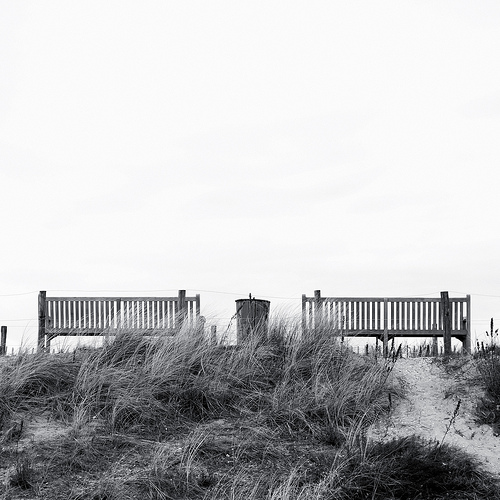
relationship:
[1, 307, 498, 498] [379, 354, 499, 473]
grass in sand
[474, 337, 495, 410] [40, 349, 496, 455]
bush on beach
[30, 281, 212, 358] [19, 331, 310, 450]
bench facing weeds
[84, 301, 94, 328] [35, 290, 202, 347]
vertical line on bench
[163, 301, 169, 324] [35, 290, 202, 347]
vertical line on bench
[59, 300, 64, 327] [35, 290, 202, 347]
vertical line on bench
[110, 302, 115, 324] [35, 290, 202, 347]
vertical line on bench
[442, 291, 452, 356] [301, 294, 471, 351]
post in front of bench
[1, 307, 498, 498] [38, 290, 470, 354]
grass growing high behind bench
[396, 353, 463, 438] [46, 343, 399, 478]
patch area near grass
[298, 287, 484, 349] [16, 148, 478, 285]
bench facing sky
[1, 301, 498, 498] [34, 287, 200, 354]
weeds growing in front of bench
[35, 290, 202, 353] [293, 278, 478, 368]
bench next to bench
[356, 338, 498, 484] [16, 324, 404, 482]
dirt path next to weeds